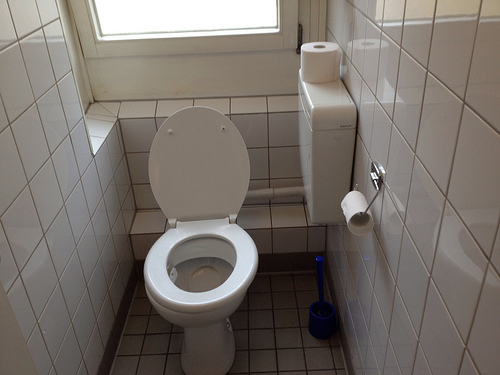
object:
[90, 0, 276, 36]
window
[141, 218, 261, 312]
toilet seat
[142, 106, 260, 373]
toilet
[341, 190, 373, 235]
paper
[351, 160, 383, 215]
holder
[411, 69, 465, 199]
tile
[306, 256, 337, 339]
toilet brush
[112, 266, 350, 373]
floor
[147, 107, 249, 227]
seat cover